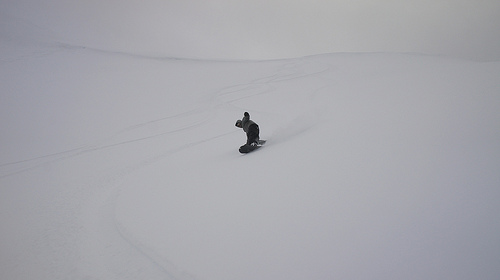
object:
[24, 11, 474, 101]
slope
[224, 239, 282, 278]
patch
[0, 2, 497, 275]
white snow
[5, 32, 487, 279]
mountain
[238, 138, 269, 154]
board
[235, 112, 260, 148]
man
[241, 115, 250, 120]
arm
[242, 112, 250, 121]
hand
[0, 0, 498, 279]
air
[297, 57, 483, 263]
snow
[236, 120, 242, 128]
hair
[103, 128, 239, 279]
lines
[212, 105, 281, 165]
arm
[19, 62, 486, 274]
ground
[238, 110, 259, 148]
gear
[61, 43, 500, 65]
line